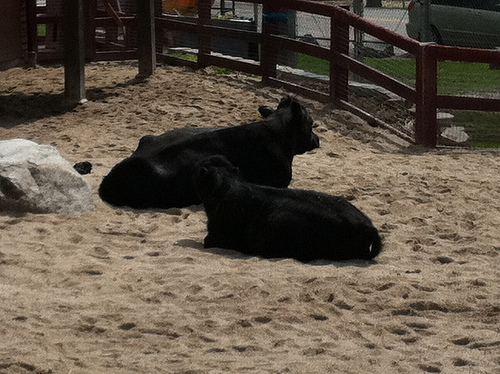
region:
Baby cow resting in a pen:
[85, 87, 392, 272]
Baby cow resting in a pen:
[78, 88, 390, 272]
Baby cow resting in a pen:
[93, 82, 393, 273]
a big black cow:
[98, 96, 320, 208]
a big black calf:
[195, 154, 382, 258]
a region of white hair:
[366, 244, 378, 253]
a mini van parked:
[405, 0, 499, 54]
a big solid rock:
[0, 134, 98, 220]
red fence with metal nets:
[0, 1, 499, 144]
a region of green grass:
[278, 40, 498, 145]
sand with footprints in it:
[2, 62, 498, 373]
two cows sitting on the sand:
[98, 92, 383, 264]